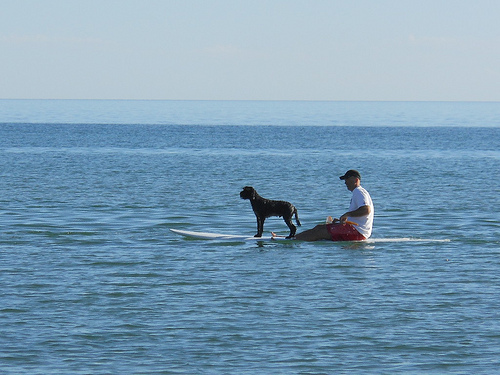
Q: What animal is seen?
A: Dog.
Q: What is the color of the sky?
A: Blue.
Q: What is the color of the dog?
A: Black.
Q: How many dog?
A: 1.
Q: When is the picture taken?
A: Daytime.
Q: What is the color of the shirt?
A: White.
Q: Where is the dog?
A: Boat.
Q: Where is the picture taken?
A: In the ocean.